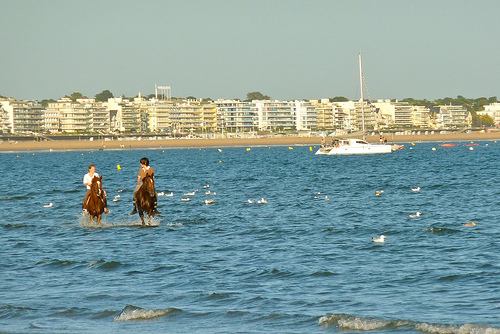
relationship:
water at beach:
[0, 139, 500, 333] [1, 0, 500, 333]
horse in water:
[86, 174, 105, 224] [0, 139, 500, 333]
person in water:
[81, 164, 109, 216] [0, 139, 500, 333]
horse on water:
[135, 172, 157, 225] [0, 139, 500, 333]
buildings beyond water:
[0, 83, 500, 142] [0, 139, 500, 333]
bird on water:
[373, 233, 388, 243] [0, 139, 500, 333]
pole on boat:
[358, 53, 367, 142] [315, 53, 394, 155]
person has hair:
[81, 164, 109, 216] [88, 164, 96, 172]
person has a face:
[81, 164, 109, 216] [90, 166, 96, 174]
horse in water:
[135, 172, 157, 225] [0, 139, 500, 333]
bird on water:
[408, 210, 423, 218] [0, 139, 500, 333]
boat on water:
[315, 53, 394, 155] [0, 139, 500, 333]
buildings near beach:
[0, 83, 500, 142] [1, 0, 500, 333]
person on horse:
[131, 156, 162, 215] [135, 172, 157, 225]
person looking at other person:
[131, 156, 162, 215] [81, 164, 109, 216]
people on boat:
[320, 138, 387, 148] [315, 53, 394, 155]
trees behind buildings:
[1, 89, 500, 126] [0, 83, 500, 142]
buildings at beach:
[0, 83, 500, 142] [1, 0, 500, 333]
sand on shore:
[1, 131, 500, 152] [1, 129, 500, 153]